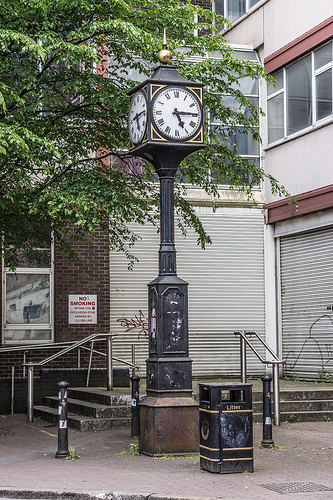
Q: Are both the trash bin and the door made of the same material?
A: Yes, both the trash bin and the door are made of metal.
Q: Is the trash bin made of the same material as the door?
A: Yes, both the trash bin and the door are made of metal.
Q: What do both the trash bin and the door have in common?
A: The material, both the trash bin and the door are metallic.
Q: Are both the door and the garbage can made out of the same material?
A: Yes, both the door and the garbage can are made of metal.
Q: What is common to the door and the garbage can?
A: The material, both the door and the garbage can are metallic.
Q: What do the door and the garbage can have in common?
A: The material, both the door and the garbage can are metallic.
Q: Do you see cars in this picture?
A: No, there are no cars.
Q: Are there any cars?
A: No, there are no cars.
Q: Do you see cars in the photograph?
A: No, there are no cars.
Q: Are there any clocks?
A: Yes, there is a clock.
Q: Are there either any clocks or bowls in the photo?
A: Yes, there is a clock.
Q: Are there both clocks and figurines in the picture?
A: No, there is a clock but no figurines.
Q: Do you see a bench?
A: No, there are no benches.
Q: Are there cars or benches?
A: No, there are no benches or cars.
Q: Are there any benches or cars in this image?
A: No, there are no benches or cars.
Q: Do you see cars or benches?
A: No, there are no benches or cars.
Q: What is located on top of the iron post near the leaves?
A: The clock is on top of the post.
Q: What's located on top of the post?
A: The clock is on top of the post.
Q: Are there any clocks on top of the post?
A: Yes, there is a clock on top of the post.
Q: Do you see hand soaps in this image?
A: No, there are no hand soaps.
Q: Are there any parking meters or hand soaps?
A: No, there are no hand soaps or parking meters.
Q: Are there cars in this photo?
A: No, there are no cars.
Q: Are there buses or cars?
A: No, there are no cars or buses.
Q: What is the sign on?
A: The sign is on the wall.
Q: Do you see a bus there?
A: No, there are no buses.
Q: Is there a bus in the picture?
A: No, there are no buses.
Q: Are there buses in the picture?
A: No, there are no buses.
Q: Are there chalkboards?
A: No, there are no chalkboards.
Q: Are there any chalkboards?
A: No, there are no chalkboards.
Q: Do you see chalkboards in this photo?
A: No, there are no chalkboards.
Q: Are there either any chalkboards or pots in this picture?
A: No, there are no chalkboards or pots.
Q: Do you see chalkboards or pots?
A: No, there are no chalkboards or pots.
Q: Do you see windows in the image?
A: Yes, there is a window.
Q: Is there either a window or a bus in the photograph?
A: Yes, there is a window.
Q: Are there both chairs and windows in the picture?
A: No, there is a window but no chairs.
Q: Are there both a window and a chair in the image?
A: No, there is a window but no chairs.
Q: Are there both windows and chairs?
A: No, there is a window but no chairs.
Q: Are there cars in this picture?
A: No, there are no cars.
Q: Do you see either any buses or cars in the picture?
A: No, there are no cars or buses.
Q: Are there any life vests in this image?
A: No, there are no life vests.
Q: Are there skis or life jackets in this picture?
A: No, there are no life jackets or skis.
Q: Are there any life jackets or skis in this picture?
A: No, there are no life jackets or skis.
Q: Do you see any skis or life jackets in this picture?
A: No, there are no life jackets or skis.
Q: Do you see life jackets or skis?
A: No, there are no life jackets or skis.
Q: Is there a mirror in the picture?
A: No, there are no mirrors.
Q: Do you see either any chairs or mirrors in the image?
A: No, there are no mirrors or chairs.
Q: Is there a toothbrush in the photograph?
A: No, there are no toothbrushes.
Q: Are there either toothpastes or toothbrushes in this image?
A: No, there are no toothbrushes or toothpastes.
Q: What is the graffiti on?
A: The graffiti is on the wall.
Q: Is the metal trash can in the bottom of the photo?
A: Yes, the trash bin is in the bottom of the image.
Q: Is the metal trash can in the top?
A: No, the trash bin is in the bottom of the image.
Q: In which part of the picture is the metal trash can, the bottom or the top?
A: The trash bin is in the bottom of the image.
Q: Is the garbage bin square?
A: Yes, the garbage bin is square.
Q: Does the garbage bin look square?
A: Yes, the garbage bin is square.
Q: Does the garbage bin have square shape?
A: Yes, the garbage bin is square.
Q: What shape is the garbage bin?
A: The garbage bin is square.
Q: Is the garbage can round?
A: No, the garbage can is square.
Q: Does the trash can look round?
A: No, the trash can is square.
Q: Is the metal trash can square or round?
A: The garbage can is square.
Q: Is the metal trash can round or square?
A: The garbage can is square.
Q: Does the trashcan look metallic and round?
A: No, the trashcan is metallic but square.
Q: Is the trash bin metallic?
A: Yes, the trash bin is metallic.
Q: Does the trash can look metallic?
A: Yes, the trash can is metallic.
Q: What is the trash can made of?
A: The trashcan is made of metal.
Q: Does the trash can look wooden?
A: No, the trash can is metallic.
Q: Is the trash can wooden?
A: No, the trash can is metallic.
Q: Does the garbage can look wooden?
A: No, the garbage can is metallic.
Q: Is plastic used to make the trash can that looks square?
A: No, the trash bin is made of metal.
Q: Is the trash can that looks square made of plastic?
A: No, the trash bin is made of metal.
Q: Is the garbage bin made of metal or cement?
A: The garbage bin is made of metal.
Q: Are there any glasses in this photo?
A: No, there are no glasses.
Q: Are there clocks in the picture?
A: Yes, there is a clock.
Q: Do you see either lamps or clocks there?
A: Yes, there is a clock.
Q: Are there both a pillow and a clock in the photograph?
A: No, there is a clock but no pillows.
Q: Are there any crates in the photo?
A: No, there are no crates.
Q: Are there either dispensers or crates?
A: No, there are no crates or dispensers.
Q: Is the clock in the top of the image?
A: Yes, the clock is in the top of the image.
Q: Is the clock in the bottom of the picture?
A: No, the clock is in the top of the image.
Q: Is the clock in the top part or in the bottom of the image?
A: The clock is in the top of the image.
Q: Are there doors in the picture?
A: Yes, there is a door.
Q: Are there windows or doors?
A: Yes, there is a door.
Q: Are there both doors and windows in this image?
A: Yes, there are both a door and a window.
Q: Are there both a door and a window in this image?
A: Yes, there are both a door and a window.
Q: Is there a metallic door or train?
A: Yes, there is a metal door.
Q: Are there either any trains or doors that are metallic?
A: Yes, the door is metallic.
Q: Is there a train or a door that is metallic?
A: Yes, the door is metallic.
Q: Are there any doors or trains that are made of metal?
A: Yes, the door is made of metal.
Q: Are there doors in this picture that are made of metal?
A: Yes, there is a door that is made of metal.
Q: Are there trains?
A: No, there are no trains.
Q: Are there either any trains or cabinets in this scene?
A: No, there are no trains or cabinets.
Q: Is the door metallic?
A: Yes, the door is metallic.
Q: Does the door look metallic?
A: Yes, the door is metallic.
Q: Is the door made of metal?
A: Yes, the door is made of metal.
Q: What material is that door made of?
A: The door is made of metal.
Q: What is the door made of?
A: The door is made of metal.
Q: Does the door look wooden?
A: No, the door is metallic.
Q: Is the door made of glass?
A: No, the door is made of metal.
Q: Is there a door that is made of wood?
A: No, there is a door but it is made of metal.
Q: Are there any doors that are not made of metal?
A: No, there is a door but it is made of metal.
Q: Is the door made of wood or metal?
A: The door is made of metal.